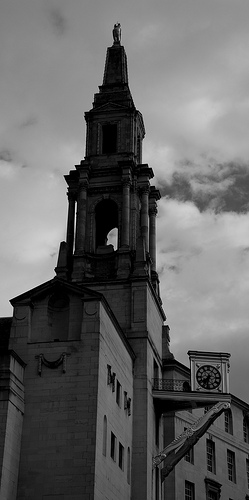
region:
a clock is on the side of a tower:
[59, 18, 236, 473]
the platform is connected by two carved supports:
[148, 386, 231, 483]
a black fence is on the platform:
[154, 347, 230, 407]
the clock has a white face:
[195, 363, 221, 390]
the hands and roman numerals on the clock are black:
[196, 363, 221, 391]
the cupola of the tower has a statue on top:
[93, 20, 130, 89]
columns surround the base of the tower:
[62, 161, 159, 278]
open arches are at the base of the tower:
[89, 189, 123, 256]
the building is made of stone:
[2, 44, 246, 493]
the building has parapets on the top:
[161, 355, 248, 412]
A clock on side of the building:
[182, 344, 230, 395]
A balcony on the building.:
[154, 367, 187, 396]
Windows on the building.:
[199, 435, 244, 489]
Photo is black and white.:
[56, 326, 219, 467]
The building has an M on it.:
[30, 349, 71, 383]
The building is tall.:
[67, 17, 163, 376]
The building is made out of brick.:
[40, 385, 88, 483]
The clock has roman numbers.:
[183, 348, 227, 401]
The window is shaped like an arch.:
[98, 406, 111, 462]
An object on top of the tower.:
[109, 22, 125, 45]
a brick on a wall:
[73, 472, 84, 480]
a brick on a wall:
[66, 485, 81, 496]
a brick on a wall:
[49, 484, 65, 495]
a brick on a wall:
[57, 473, 70, 486]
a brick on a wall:
[70, 456, 83, 466]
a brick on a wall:
[60, 432, 70, 436]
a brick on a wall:
[41, 447, 59, 456]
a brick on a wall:
[46, 430, 63, 441]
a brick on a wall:
[27, 446, 42, 454]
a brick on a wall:
[32, 424, 48, 435]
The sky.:
[0, 1, 248, 404]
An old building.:
[0, 21, 248, 499]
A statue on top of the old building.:
[112, 21, 121, 44]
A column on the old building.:
[119, 177, 131, 249]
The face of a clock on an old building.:
[193, 360, 222, 392]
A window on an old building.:
[223, 407, 233, 435]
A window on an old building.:
[226, 448, 236, 484]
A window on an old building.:
[205, 438, 216, 474]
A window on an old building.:
[183, 426, 194, 463]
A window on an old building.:
[184, 479, 194, 498]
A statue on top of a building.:
[112, 23, 121, 42]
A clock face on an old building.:
[194, 361, 222, 391]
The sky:
[0, 1, 247, 404]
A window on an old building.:
[110, 430, 117, 462]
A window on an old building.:
[115, 379, 121, 408]